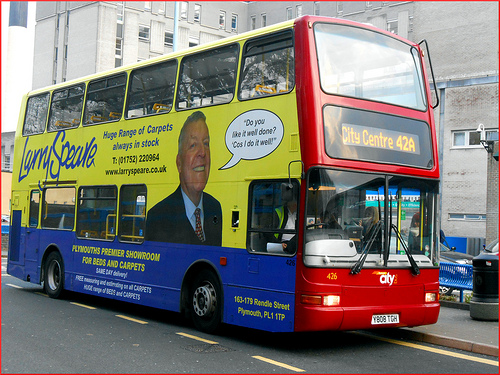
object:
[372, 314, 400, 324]
license plate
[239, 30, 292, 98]
windows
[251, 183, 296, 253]
window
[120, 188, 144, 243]
window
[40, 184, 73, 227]
window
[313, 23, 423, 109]
window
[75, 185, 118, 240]
window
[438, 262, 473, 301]
bench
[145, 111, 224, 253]
man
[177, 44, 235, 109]
window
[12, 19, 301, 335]
side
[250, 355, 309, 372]
line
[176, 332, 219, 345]
line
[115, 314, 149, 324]
line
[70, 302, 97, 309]
line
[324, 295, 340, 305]
light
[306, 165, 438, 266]
window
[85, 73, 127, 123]
window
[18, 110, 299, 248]
advertisements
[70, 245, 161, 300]
advertisements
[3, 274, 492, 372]
road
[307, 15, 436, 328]
front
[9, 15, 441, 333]
bus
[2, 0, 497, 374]
picture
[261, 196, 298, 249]
bus driver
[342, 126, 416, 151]
route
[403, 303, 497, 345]
sidewalk